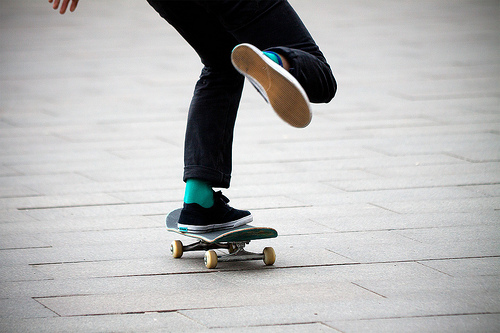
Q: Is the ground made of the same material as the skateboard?
A: No, the ground is made of cement and the skateboard is made of wood.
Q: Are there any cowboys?
A: No, there are no cowboys.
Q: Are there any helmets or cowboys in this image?
A: No, there are no cowboys or helmets.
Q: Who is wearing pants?
A: The skater is wearing pants.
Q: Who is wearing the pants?
A: The skater is wearing pants.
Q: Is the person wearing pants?
A: Yes, the skater is wearing pants.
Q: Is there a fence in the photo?
A: No, there are no fences.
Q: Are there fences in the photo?
A: No, there are no fences.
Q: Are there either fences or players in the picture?
A: No, there are no fences or players.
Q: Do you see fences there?
A: No, there are no fences.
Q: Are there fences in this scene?
A: No, there are no fences.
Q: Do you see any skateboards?
A: Yes, there is a skateboard.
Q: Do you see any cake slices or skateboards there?
A: Yes, there is a skateboard.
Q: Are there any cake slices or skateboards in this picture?
A: Yes, there is a skateboard.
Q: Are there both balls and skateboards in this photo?
A: No, there is a skateboard but no balls.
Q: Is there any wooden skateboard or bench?
A: Yes, there is a wood skateboard.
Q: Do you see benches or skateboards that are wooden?
A: Yes, the skateboard is wooden.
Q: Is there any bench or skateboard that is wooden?
A: Yes, the skateboard is wooden.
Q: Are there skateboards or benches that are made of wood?
A: Yes, the skateboard is made of wood.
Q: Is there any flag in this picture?
A: No, there are no flags.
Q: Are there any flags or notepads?
A: No, there are no flags or notepads.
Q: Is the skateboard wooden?
A: Yes, the skateboard is wooden.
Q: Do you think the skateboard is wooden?
A: Yes, the skateboard is wooden.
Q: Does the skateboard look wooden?
A: Yes, the skateboard is wooden.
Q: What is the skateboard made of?
A: The skateboard is made of wood.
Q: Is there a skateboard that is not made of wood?
A: No, there is a skateboard but it is made of wood.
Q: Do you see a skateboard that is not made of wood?
A: No, there is a skateboard but it is made of wood.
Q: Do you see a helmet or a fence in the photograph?
A: No, there are no fences or helmets.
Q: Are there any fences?
A: No, there are no fences.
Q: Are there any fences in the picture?
A: No, there are no fences.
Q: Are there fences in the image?
A: No, there are no fences.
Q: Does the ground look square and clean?
A: Yes, the ground is square and clean.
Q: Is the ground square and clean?
A: Yes, the ground is square and clean.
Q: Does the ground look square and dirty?
A: No, the ground is square but clean.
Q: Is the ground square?
A: Yes, the ground is square.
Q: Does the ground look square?
A: Yes, the ground is square.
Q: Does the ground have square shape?
A: Yes, the ground is square.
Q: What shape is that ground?
A: The ground is square.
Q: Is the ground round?
A: No, the ground is square.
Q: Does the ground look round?
A: No, the ground is square.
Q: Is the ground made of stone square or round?
A: The ground is square.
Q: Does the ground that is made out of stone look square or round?
A: The ground is square.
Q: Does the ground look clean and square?
A: Yes, the ground is clean and square.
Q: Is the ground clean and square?
A: Yes, the ground is clean and square.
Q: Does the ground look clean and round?
A: No, the ground is clean but square.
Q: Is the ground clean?
A: Yes, the ground is clean.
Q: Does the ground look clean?
A: Yes, the ground is clean.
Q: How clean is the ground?
A: The ground is clean.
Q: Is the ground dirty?
A: No, the ground is clean.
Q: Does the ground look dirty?
A: No, the ground is clean.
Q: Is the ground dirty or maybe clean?
A: The ground is clean.